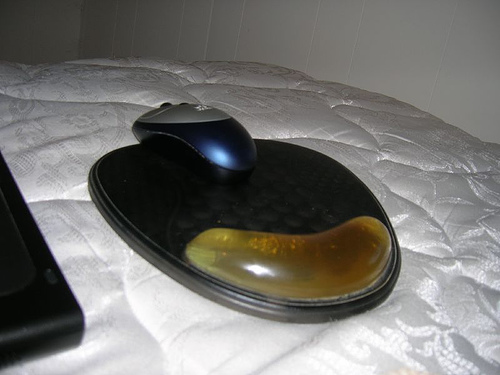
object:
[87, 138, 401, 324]
mouse pad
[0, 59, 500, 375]
bed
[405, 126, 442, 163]
wall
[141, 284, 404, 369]
light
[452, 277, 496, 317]
mattress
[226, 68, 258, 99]
mattress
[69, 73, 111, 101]
mattress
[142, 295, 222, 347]
mattress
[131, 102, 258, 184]
mouse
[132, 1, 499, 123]
wall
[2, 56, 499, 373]
white mattress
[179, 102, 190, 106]
wheel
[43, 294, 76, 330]
edge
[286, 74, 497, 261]
blanket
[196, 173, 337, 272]
mousepad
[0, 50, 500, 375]
blanket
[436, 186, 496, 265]
flower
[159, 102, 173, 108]
scroller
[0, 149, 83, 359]
laptop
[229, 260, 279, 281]
reflected light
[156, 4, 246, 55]
bars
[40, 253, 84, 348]
board